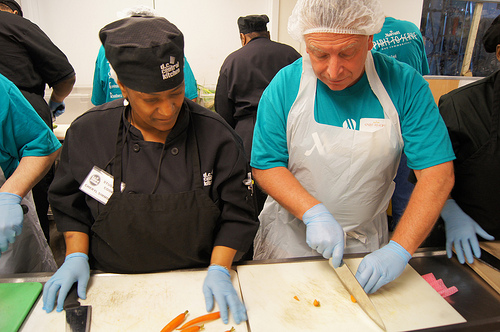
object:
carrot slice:
[159, 308, 188, 331]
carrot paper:
[234, 256, 471, 332]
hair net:
[285, 0, 386, 41]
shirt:
[248, 46, 461, 172]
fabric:
[227, 57, 262, 98]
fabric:
[6, 29, 43, 59]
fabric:
[458, 91, 496, 135]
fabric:
[385, 25, 410, 51]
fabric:
[135, 43, 162, 72]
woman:
[38, 13, 262, 328]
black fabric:
[127, 201, 175, 257]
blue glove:
[40, 250, 91, 312]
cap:
[236, 13, 271, 35]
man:
[247, 1, 461, 298]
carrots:
[174, 310, 220, 331]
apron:
[249, 48, 406, 262]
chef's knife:
[327, 255, 387, 331]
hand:
[352, 239, 412, 296]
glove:
[438, 197, 494, 265]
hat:
[97, 11, 186, 94]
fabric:
[324, 90, 356, 118]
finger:
[54, 280, 78, 313]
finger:
[202, 286, 214, 313]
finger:
[213, 292, 229, 325]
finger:
[330, 242, 344, 270]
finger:
[443, 239, 455, 259]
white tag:
[77, 164, 127, 207]